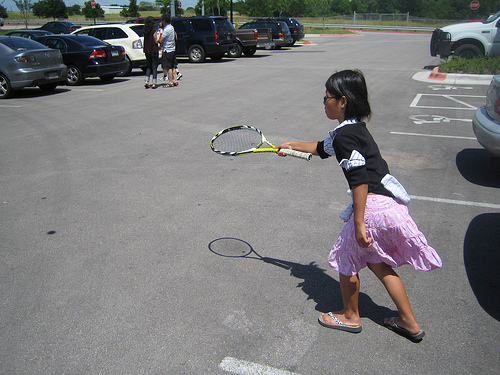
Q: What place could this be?
A: It is a pavement.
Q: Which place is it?
A: It is a pavement.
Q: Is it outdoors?
A: Yes, it is outdoors.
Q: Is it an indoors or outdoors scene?
A: It is outdoors.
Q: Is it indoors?
A: No, it is outdoors.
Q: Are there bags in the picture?
A: No, there are no bags.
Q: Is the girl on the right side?
A: Yes, the girl is on the right of the image.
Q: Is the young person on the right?
A: Yes, the girl is on the right of the image.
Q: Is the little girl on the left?
A: No, the girl is on the right of the image.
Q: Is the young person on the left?
A: No, the girl is on the right of the image.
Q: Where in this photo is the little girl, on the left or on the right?
A: The girl is on the right of the image.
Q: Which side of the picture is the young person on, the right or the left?
A: The girl is on the right of the image.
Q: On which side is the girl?
A: The girl is on the right of the image.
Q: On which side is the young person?
A: The girl is on the right of the image.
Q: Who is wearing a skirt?
A: The girl is wearing a skirt.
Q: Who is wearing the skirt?
A: The girl is wearing a skirt.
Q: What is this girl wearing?
A: The girl is wearing a skirt.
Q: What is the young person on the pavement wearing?
A: The girl is wearing a skirt.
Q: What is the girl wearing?
A: The girl is wearing a skirt.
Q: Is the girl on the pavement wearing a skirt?
A: Yes, the girl is wearing a skirt.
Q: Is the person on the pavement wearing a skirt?
A: Yes, the girl is wearing a skirt.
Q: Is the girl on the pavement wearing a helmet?
A: No, the girl is wearing a skirt.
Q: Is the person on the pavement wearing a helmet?
A: No, the girl is wearing a skirt.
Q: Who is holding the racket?
A: The girl is holding the racket.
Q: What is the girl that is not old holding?
A: The girl is holding the racket.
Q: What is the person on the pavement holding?
A: The girl is holding the racket.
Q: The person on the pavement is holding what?
A: The girl is holding the racket.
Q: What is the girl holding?
A: The girl is holding the racket.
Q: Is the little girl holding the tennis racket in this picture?
A: Yes, the girl is holding the tennis racket.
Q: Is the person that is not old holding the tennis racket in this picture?
A: Yes, the girl is holding the tennis racket.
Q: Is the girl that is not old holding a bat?
A: No, the girl is holding the tennis racket.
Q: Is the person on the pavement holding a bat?
A: No, the girl is holding the tennis racket.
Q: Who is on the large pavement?
A: The girl is on the pavement.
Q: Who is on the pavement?
A: The girl is on the pavement.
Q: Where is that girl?
A: The girl is on the pavement.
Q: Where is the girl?
A: The girl is on the pavement.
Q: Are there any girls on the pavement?
A: Yes, there is a girl on the pavement.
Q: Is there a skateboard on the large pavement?
A: No, there is a girl on the pavement.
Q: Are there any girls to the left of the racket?
A: No, the girl is to the right of the racket.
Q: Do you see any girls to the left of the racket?
A: No, the girl is to the right of the racket.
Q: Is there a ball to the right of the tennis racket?
A: No, there is a girl to the right of the tennis racket.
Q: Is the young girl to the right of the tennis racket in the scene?
A: Yes, the girl is to the right of the tennis racket.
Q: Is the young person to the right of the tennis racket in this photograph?
A: Yes, the girl is to the right of the tennis racket.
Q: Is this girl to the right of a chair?
A: No, the girl is to the right of the tennis racket.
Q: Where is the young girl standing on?
A: The girl is standing on the pavement.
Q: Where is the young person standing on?
A: The girl is standing on the pavement.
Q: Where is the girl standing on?
A: The girl is standing on the pavement.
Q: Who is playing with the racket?
A: The girl is playing with the racket.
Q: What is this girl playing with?
A: The girl is playing with a racket.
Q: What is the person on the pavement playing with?
A: The girl is playing with a racket.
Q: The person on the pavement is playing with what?
A: The girl is playing with a racket.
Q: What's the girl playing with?
A: The girl is playing with a racket.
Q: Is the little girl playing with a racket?
A: Yes, the girl is playing with a racket.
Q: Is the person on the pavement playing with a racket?
A: Yes, the girl is playing with a racket.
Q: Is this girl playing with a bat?
A: No, the girl is playing with a racket.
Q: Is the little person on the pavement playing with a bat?
A: No, the girl is playing with a racket.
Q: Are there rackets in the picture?
A: Yes, there is a racket.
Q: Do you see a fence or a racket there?
A: Yes, there is a racket.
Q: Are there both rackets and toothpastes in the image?
A: No, there is a racket but no toothpastes.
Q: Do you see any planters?
A: No, there are no planters.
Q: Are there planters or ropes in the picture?
A: No, there are no planters or ropes.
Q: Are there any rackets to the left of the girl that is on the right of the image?
A: Yes, there is a racket to the left of the girl.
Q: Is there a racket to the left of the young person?
A: Yes, there is a racket to the left of the girl.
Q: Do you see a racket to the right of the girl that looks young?
A: No, the racket is to the left of the girl.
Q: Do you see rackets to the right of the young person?
A: No, the racket is to the left of the girl.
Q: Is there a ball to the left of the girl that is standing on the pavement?
A: No, there is a racket to the left of the girl.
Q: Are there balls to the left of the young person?
A: No, there is a racket to the left of the girl.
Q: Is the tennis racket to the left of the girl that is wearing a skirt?
A: Yes, the tennis racket is to the left of the girl.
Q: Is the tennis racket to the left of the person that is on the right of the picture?
A: Yes, the tennis racket is to the left of the girl.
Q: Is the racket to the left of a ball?
A: No, the racket is to the left of the girl.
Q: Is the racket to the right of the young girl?
A: No, the racket is to the left of the girl.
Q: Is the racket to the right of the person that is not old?
A: No, the racket is to the left of the girl.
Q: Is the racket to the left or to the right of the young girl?
A: The racket is to the left of the girl.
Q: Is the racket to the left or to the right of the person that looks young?
A: The racket is to the left of the girl.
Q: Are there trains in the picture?
A: No, there are no trains.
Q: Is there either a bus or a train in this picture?
A: No, there are no trains or buses.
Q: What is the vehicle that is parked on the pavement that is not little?
A: The vehicle is a car.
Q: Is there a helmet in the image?
A: No, there are no helmets.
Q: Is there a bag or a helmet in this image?
A: No, there are no helmets or bags.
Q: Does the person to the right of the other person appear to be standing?
A: Yes, the person is standing.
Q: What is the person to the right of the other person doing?
A: The person is standing.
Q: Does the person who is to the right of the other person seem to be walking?
A: No, the person is standing.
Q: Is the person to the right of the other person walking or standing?
A: The person is standing.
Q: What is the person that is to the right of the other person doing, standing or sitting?
A: The person is standing.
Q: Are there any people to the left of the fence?
A: Yes, there is a person to the left of the fence.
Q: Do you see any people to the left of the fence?
A: Yes, there is a person to the left of the fence.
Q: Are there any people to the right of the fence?
A: No, the person is to the left of the fence.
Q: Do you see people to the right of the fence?
A: No, the person is to the left of the fence.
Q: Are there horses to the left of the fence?
A: No, there is a person to the left of the fence.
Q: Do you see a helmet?
A: No, there are no helmets.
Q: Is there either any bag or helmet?
A: No, there are no helmets or bags.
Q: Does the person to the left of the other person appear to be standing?
A: Yes, the person is standing.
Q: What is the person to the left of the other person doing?
A: The person is standing.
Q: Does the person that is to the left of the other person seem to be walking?
A: No, the person is standing.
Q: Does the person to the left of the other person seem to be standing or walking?
A: The person is standing.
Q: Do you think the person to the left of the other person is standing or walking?
A: The person is standing.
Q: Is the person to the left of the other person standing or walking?
A: The person is standing.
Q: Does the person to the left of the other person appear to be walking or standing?
A: The person is standing.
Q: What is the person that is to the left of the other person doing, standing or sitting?
A: The person is standing.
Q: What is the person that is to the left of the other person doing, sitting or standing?
A: The person is standing.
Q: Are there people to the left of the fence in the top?
A: Yes, there is a person to the left of the fence.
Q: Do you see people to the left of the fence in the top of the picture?
A: Yes, there is a person to the left of the fence.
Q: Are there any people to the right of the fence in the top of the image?
A: No, the person is to the left of the fence.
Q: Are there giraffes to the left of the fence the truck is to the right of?
A: No, there is a person to the left of the fence.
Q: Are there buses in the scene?
A: No, there are no buses.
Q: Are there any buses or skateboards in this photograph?
A: No, there are no buses or skateboards.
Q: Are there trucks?
A: Yes, there is a truck.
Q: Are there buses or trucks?
A: Yes, there is a truck.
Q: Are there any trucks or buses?
A: Yes, there is a truck.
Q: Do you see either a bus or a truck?
A: Yes, there is a truck.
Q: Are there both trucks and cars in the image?
A: Yes, there are both a truck and a car.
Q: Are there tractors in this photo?
A: No, there are no tractors.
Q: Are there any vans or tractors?
A: No, there are no tractors or vans.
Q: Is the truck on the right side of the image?
A: Yes, the truck is on the right of the image.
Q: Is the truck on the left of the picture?
A: No, the truck is on the right of the image.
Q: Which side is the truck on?
A: The truck is on the right of the image.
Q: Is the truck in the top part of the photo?
A: Yes, the truck is in the top of the image.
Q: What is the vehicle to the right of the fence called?
A: The vehicle is a truck.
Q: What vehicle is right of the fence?
A: The vehicle is a truck.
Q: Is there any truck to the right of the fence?
A: Yes, there is a truck to the right of the fence.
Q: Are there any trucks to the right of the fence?
A: Yes, there is a truck to the right of the fence.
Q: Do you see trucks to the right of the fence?
A: Yes, there is a truck to the right of the fence.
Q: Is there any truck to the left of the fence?
A: No, the truck is to the right of the fence.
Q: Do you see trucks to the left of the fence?
A: No, the truck is to the right of the fence.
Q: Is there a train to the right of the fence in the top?
A: No, there is a truck to the right of the fence.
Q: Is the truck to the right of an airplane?
A: No, the truck is to the right of a fence.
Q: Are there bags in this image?
A: No, there are no bags.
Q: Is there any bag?
A: No, there are no bags.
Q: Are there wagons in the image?
A: No, there are no wagons.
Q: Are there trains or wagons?
A: No, there are no wagons or trains.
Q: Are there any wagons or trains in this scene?
A: No, there are no wagons or trains.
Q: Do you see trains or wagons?
A: No, there are no wagons or trains.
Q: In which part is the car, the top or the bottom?
A: The car is in the top of the image.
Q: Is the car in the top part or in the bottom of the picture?
A: The car is in the top of the image.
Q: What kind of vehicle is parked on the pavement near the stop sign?
A: The vehicle is a car.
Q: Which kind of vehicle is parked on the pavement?
A: The vehicle is a car.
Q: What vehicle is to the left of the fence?
A: The vehicle is a car.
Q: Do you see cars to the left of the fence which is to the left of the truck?
A: Yes, there is a car to the left of the fence.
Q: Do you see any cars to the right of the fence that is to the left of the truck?
A: No, the car is to the left of the fence.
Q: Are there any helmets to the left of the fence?
A: No, there is a car to the left of the fence.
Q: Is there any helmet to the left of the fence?
A: No, there is a car to the left of the fence.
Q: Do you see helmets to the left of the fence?
A: No, there is a car to the left of the fence.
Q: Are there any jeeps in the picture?
A: No, there are no jeeps.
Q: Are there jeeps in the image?
A: No, there are no jeeps.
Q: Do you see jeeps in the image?
A: No, there are no jeeps.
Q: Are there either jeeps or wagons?
A: No, there are no jeeps or wagons.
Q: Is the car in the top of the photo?
A: Yes, the car is in the top of the image.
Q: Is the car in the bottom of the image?
A: No, the car is in the top of the image.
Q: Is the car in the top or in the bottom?
A: The car is in the top of the image.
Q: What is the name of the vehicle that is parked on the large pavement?
A: The vehicle is a car.